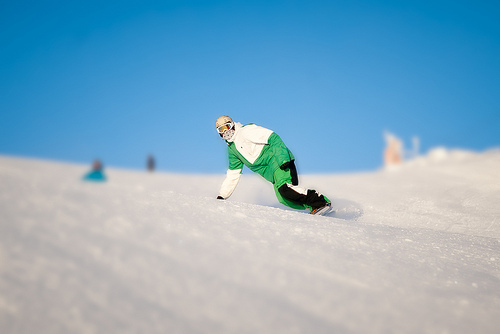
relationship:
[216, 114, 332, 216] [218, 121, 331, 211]
person wearing snow suit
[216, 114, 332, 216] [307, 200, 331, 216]
person riding snowboard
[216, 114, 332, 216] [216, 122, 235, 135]
person wearing ski goggles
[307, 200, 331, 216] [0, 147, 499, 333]
snowboard cutting through snow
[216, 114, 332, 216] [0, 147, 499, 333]
person riding down snow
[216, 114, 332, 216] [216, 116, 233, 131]
person wearing helmet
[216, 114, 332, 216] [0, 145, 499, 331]
person on top of mountain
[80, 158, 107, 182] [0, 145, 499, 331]
person on top of mountain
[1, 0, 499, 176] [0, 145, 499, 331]
sky above mountain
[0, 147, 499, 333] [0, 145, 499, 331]
snow on top of mountain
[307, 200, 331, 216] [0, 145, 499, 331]
snowboard on top of mountain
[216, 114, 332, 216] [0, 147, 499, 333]
person touching snow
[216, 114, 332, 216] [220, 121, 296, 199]
person wearing ski jacket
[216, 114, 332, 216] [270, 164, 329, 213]
person wearing pants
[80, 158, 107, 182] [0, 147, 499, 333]
person standing in snow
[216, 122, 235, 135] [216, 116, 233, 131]
ski goggles below helmet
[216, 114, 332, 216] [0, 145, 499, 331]
person going down mountain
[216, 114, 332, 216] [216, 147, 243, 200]
person has arm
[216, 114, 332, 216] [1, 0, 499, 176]
person against sky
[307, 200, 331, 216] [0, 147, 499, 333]
snowboard on top of snow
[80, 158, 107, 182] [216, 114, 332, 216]
person behind person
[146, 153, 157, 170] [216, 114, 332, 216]
figure behind person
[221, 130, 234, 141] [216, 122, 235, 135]
bandana under ski goggles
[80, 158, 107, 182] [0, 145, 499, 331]
person standing on mountain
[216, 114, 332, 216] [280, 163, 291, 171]
person wearing glove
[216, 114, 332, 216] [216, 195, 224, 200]
person wearing glove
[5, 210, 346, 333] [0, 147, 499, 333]
tracks on surface of snow